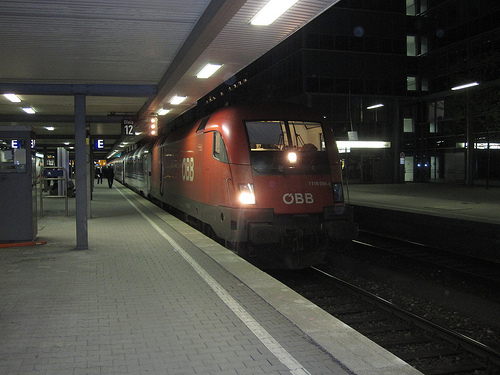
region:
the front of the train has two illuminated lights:
[226, 111, 349, 261]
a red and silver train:
[107, 100, 354, 269]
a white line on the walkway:
[110, 183, 315, 374]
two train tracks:
[291, 225, 498, 371]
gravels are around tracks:
[286, 224, 499, 374]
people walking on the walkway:
[93, 159, 117, 189]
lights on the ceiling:
[1, 17, 289, 160]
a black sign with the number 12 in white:
[117, 117, 138, 138]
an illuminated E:
[7, 135, 21, 150]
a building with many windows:
[224, 0, 495, 192]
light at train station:
[41, 118, 56, 138]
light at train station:
[16, 103, 43, 118]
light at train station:
[1, 91, 25, 107]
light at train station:
[140, 108, 164, 138]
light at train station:
[155, 103, 170, 120]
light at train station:
[163, 89, 189, 111]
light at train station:
[191, 56, 223, 91]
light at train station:
[247, 3, 294, 34]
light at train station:
[87, 130, 110, 155]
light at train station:
[0, 132, 25, 157]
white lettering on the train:
[258, 185, 330, 209]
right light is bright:
[213, 170, 272, 217]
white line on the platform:
[123, 282, 292, 374]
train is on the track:
[283, 123, 498, 321]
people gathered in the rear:
[95, 155, 122, 193]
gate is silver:
[36, 145, 84, 214]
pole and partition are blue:
[50, 83, 152, 239]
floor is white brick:
[50, 248, 205, 373]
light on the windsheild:
[273, 148, 313, 176]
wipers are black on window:
[251, 132, 326, 150]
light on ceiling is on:
[256, 5, 285, 24]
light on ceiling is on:
[203, 58, 230, 86]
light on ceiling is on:
[169, 92, 192, 107]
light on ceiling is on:
[158, 108, 174, 118]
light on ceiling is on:
[4, 89, 29, 103]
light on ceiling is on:
[21, 101, 49, 122]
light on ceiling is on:
[42, 123, 61, 132]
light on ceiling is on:
[61, 132, 72, 150]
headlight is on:
[234, 183, 268, 215]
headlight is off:
[328, 175, 359, 219]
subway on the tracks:
[141, 100, 388, 291]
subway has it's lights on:
[205, 151, 319, 276]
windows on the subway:
[245, 116, 361, 196]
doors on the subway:
[136, 143, 213, 224]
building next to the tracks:
[336, 0, 494, 198]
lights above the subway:
[148, 43, 237, 103]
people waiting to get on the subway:
[84, 150, 131, 207]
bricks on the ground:
[89, 260, 211, 353]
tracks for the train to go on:
[354, 223, 499, 373]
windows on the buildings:
[388, 23, 435, 96]